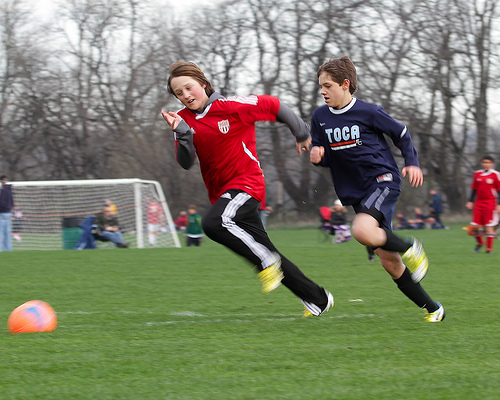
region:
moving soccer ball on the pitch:
[5, 292, 60, 339]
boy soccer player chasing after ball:
[155, 62, 341, 319]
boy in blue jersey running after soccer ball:
[295, 55, 464, 327]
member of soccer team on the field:
[464, 151, 499, 257]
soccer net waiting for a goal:
[0, 153, 190, 272]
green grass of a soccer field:
[100, 257, 207, 339]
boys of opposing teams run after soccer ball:
[6, 58, 499, 349]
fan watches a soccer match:
[314, 196, 351, 246]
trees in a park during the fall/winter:
[5, 5, 135, 162]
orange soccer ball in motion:
[7, 292, 63, 346]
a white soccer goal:
[5, 176, 187, 249]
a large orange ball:
[9, 289, 61, 335]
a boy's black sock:
[376, 228, 411, 254]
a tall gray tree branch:
[252, 2, 354, 220]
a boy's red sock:
[482, 233, 496, 252]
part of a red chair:
[317, 205, 331, 224]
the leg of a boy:
[198, 185, 276, 270]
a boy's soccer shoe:
[402, 238, 432, 282]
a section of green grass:
[0, 245, 499, 398]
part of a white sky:
[28, 0, 57, 17]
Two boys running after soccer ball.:
[159, 57, 446, 322]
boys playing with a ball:
[135, 53, 452, 343]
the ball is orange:
[2, 297, 60, 337]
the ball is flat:
[4, 294, 66, 338]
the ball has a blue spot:
[4, 295, 56, 335]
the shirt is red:
[168, 91, 283, 203]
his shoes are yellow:
[254, 255, 316, 319]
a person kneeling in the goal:
[0, 177, 188, 248]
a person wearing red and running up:
[463, 155, 496, 252]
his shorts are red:
[468, 202, 498, 228]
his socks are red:
[472, 232, 495, 252]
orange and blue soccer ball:
[10, 294, 65, 331]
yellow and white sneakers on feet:
[258, 263, 286, 292]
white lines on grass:
[136, 287, 226, 347]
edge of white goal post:
[127, 173, 182, 258]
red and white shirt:
[162, 106, 287, 223]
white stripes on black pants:
[213, 205, 283, 274]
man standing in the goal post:
[63, 185, 138, 254]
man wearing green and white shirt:
[183, 205, 210, 243]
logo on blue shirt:
[366, 171, 410, 191]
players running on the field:
[144, 55, 441, 323]